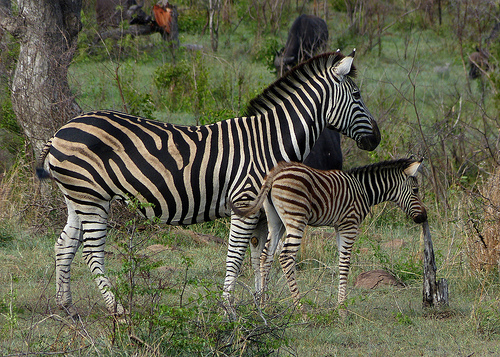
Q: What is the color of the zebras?
A: White and black.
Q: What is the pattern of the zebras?
A: Stripes.